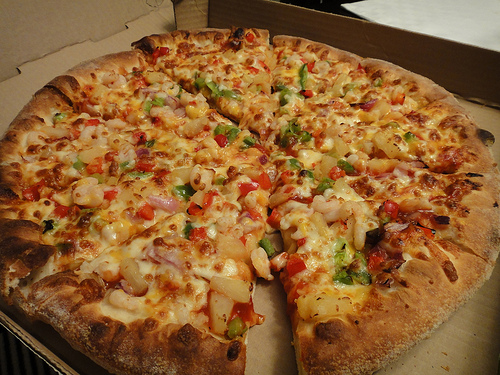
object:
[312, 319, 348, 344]
bubble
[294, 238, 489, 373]
crust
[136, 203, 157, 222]
tomato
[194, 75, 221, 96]
peppers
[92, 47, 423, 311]
seasoning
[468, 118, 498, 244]
crust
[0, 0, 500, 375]
box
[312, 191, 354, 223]
cheese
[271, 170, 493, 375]
pizza triangle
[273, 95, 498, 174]
pizza triangle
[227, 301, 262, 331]
sauce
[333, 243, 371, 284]
pepper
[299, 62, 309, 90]
pepper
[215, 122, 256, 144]
pepper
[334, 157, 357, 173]
pepper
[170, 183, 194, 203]
pepper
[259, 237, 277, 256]
pepper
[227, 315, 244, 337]
pepper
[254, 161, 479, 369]
slice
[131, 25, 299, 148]
slice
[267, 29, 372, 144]
slice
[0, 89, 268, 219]
slice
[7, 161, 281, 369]
slice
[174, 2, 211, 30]
corner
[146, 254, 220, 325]
cheese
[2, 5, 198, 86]
fold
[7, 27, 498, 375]
pizza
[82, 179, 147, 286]
onion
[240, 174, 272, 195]
tomato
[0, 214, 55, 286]
crust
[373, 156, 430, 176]
onion